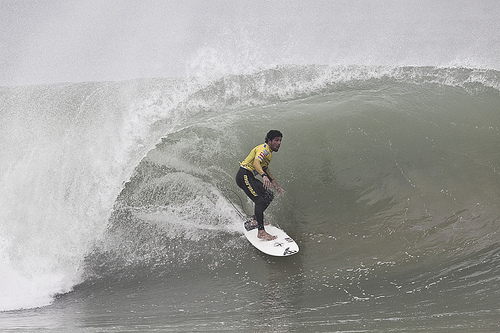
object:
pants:
[235, 168, 274, 230]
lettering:
[243, 175, 258, 196]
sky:
[0, 0, 500, 78]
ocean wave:
[49, 58, 500, 331]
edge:
[0, 66, 499, 100]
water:
[319, 76, 499, 331]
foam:
[0, 55, 231, 316]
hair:
[265, 130, 282, 144]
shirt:
[241, 143, 273, 175]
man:
[236, 129, 282, 241]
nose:
[281, 246, 300, 257]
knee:
[266, 190, 274, 200]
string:
[221, 194, 244, 218]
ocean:
[0, 63, 497, 328]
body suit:
[234, 143, 275, 230]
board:
[242, 217, 299, 256]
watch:
[261, 173, 267, 177]